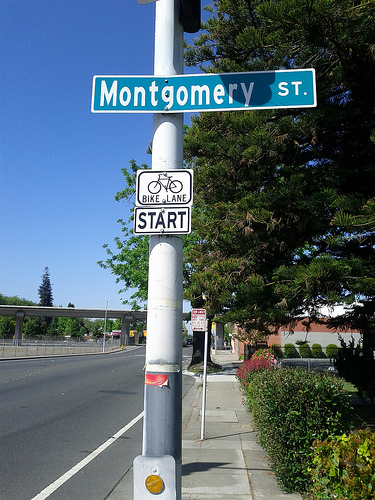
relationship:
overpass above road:
[20, 304, 120, 322] [16, 377, 96, 454]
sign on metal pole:
[90, 68, 317, 113] [132, 0, 187, 496]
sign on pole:
[135, 168, 193, 205] [137, 0, 180, 493]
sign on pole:
[190, 307, 207, 331] [200, 318, 209, 440]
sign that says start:
[134, 211, 194, 236] [135, 211, 185, 230]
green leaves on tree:
[195, 120, 306, 304] [68, 7, 372, 359]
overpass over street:
[20, 305, 117, 322] [17, 338, 142, 440]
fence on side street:
[7, 337, 121, 355] [8, 348, 155, 424]